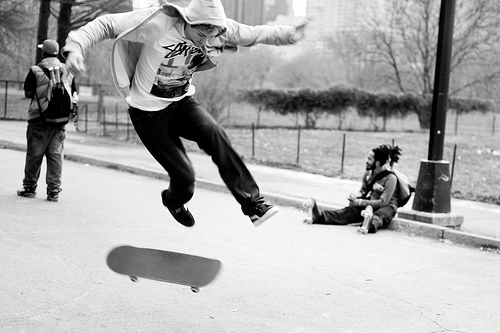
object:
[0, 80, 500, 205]
fence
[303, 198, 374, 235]
rollerskates.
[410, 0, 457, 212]
pole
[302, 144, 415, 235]
man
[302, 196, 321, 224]
skate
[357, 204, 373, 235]
skate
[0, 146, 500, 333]
grey concrete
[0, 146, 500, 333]
road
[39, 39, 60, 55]
baseball cap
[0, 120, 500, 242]
sidewalk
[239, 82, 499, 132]
plants fence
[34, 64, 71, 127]
backpack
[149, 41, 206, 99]
print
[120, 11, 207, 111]
shirt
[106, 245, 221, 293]
skateboard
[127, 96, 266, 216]
pants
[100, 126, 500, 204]
grass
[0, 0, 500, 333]
park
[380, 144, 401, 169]
pony tail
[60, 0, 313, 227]
man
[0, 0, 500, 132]
tree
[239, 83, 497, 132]
vines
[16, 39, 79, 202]
man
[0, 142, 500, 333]
curb